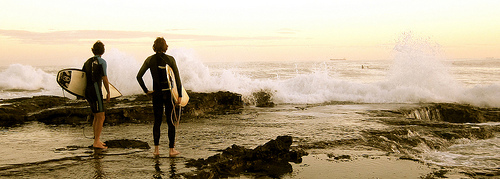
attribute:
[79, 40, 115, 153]
man — standing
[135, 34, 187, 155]
man — standing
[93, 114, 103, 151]
leg — man's leg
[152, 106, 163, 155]
leg — man's leg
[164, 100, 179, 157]
leg — man's leg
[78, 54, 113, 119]
gear — dark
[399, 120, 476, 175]
water — white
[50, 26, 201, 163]
surfer — standing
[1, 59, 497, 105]
water — splashing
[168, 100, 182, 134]
cable — hanging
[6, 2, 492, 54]
sky — orange, cloudy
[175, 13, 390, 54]
clouds — white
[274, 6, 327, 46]
sky — blue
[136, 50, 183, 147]
sportinggear — dark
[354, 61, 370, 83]
object — tiny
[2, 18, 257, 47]
clouds — white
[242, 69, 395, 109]
water — standing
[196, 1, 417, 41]
sky — blue